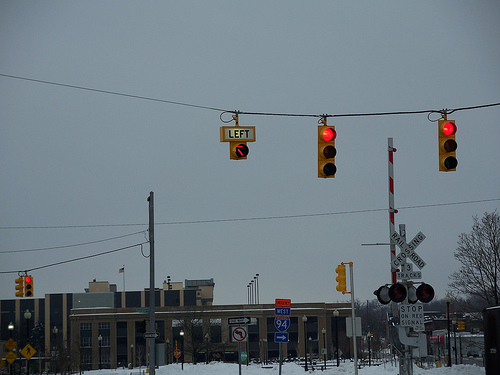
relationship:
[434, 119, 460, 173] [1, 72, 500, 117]
traffic light attached to wire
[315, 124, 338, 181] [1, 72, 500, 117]
traffic light attached to wire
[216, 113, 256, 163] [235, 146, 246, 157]
traffic light with an arrow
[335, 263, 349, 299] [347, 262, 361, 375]
traffic light attached to pole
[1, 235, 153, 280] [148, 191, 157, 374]
wire attached to a pole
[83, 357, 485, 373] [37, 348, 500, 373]
snow on ground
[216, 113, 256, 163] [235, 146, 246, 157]
traffic light showing an arrow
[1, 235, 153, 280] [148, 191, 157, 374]
wire attached to pole